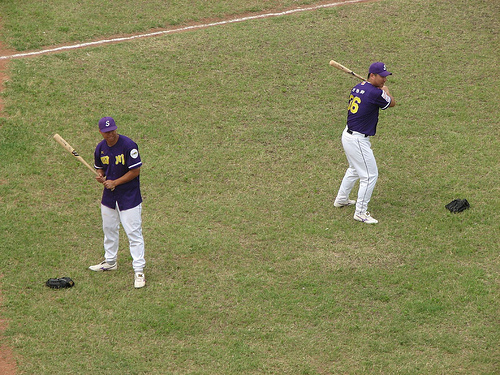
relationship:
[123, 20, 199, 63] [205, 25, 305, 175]
line on field